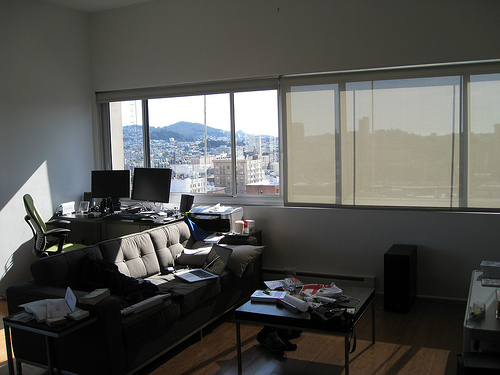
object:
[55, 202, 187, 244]
desk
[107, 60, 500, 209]
window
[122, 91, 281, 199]
city view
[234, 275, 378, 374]
coffee table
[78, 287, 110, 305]
book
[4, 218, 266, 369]
couch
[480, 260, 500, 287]
wii games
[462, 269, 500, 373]
table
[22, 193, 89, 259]
chair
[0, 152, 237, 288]
sun shining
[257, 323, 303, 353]
tennis shoes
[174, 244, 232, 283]
laptop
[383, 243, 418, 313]
speaker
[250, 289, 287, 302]
book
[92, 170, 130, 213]
computers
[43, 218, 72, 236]
armrest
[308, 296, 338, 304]
wii controler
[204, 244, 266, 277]
pillow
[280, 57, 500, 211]
curtains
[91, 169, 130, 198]
computer monitor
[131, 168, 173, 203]
computer monitor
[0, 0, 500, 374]
room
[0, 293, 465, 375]
floor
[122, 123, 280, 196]
building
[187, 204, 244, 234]
printer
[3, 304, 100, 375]
end table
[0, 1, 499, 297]
wall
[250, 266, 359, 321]
trash